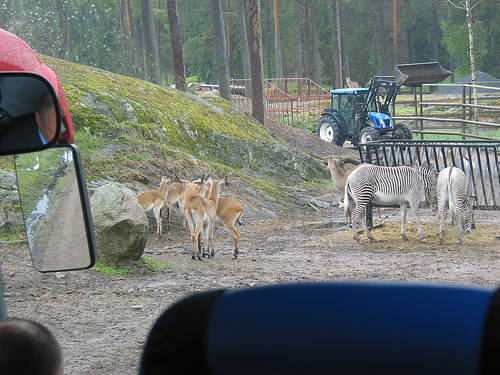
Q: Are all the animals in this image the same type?
A: No, they are antelopes and zebras.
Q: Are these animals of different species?
A: Yes, they are antelopes and zebras.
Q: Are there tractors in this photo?
A: Yes, there is a tractor.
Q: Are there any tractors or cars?
A: Yes, there is a tractor.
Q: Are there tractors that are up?
A: Yes, there is a tractor that is up.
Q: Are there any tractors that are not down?
A: Yes, there is a tractor that is up.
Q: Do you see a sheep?
A: No, there is no sheep.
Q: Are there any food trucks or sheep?
A: No, there are no sheep or food trucks.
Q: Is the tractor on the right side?
A: Yes, the tractor is on the right of the image.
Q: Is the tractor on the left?
A: No, the tractor is on the right of the image.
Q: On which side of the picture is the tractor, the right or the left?
A: The tractor is on the right of the image.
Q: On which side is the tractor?
A: The tractor is on the right of the image.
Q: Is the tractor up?
A: Yes, the tractor is up.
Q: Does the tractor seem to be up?
A: Yes, the tractor is up.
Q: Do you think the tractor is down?
A: No, the tractor is up.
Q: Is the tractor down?
A: No, the tractor is up.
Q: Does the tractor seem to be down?
A: No, the tractor is up.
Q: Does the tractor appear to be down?
A: No, the tractor is up.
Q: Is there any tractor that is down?
A: No, there is a tractor but it is up.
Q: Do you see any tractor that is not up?
A: No, there is a tractor but it is up.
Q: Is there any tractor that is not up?
A: No, there is a tractor but it is up.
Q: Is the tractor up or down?
A: The tractor is up.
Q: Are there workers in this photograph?
A: No, there are no workers.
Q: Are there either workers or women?
A: No, there are no workers or women.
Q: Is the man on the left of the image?
A: Yes, the man is on the left of the image.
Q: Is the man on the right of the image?
A: No, the man is on the left of the image.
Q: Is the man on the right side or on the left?
A: The man is on the left of the image.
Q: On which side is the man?
A: The man is on the left of the image.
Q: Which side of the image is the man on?
A: The man is on the left of the image.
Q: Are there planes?
A: No, there are no planes.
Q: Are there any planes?
A: No, there are no planes.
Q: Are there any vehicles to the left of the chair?
A: Yes, there is a vehicle to the left of the chair.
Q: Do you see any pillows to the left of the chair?
A: No, there is a vehicle to the left of the chair.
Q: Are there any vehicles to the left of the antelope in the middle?
A: Yes, there is a vehicle to the left of the antelope.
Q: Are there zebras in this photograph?
A: Yes, there is a zebra.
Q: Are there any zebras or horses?
A: Yes, there is a zebra.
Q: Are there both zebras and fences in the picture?
A: Yes, there are both a zebra and a fence.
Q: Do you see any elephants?
A: No, there are no elephants.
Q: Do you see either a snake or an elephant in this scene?
A: No, there are no elephants or snakes.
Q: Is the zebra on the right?
A: Yes, the zebra is on the right of the image.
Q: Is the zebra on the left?
A: No, the zebra is on the right of the image.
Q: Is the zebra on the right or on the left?
A: The zebra is on the right of the image.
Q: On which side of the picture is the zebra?
A: The zebra is on the right of the image.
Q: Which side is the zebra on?
A: The zebra is on the right of the image.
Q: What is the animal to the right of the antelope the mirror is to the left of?
A: The animal is a zebra.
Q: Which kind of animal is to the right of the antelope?
A: The animal is a zebra.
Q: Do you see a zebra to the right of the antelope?
A: Yes, there is a zebra to the right of the antelope.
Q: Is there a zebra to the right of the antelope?
A: Yes, there is a zebra to the right of the antelope.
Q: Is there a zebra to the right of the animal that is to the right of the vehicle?
A: Yes, there is a zebra to the right of the antelope.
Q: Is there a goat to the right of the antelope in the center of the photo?
A: No, there is a zebra to the right of the antelope.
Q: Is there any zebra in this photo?
A: Yes, there is a zebra.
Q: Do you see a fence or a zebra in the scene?
A: Yes, there is a zebra.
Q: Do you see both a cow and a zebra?
A: No, there is a zebra but no cows.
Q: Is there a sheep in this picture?
A: No, there is no sheep.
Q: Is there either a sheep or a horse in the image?
A: No, there are no sheep or horses.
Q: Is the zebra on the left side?
A: No, the zebra is on the right of the image.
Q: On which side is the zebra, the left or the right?
A: The zebra is on the right of the image.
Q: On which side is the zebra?
A: The zebra is on the right of the image.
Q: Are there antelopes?
A: Yes, there is an antelope.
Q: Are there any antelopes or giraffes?
A: Yes, there is an antelope.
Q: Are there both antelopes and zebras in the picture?
A: Yes, there are both an antelope and a zebra.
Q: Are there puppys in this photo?
A: No, there are no puppys.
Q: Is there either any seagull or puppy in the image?
A: No, there are no puppys or seagulls.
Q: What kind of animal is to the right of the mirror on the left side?
A: The animal is an antelope.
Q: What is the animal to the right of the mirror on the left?
A: The animal is an antelope.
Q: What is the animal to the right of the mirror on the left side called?
A: The animal is an antelope.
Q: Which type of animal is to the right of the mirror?
A: The animal is an antelope.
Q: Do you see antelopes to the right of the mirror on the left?
A: Yes, there is an antelope to the right of the mirror.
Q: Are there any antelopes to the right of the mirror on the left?
A: Yes, there is an antelope to the right of the mirror.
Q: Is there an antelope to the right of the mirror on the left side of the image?
A: Yes, there is an antelope to the right of the mirror.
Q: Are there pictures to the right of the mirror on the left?
A: No, there is an antelope to the right of the mirror.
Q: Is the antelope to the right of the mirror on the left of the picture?
A: Yes, the antelope is to the right of the mirror.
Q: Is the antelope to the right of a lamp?
A: No, the antelope is to the right of the mirror.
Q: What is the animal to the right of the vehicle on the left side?
A: The animal is an antelope.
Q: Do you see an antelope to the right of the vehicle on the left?
A: Yes, there is an antelope to the right of the vehicle.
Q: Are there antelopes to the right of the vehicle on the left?
A: Yes, there is an antelope to the right of the vehicle.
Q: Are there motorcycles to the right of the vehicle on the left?
A: No, there is an antelope to the right of the vehicle.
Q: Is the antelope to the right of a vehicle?
A: Yes, the antelope is to the right of a vehicle.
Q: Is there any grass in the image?
A: Yes, there is grass.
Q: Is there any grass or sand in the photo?
A: Yes, there is grass.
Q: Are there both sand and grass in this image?
A: No, there is grass but no sand.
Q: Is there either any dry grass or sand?
A: Yes, there is dry grass.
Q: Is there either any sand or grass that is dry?
A: Yes, the grass is dry.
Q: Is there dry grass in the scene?
A: Yes, there is dry grass.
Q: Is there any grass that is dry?
A: Yes, there is grass that is dry.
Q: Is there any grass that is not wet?
A: Yes, there is dry grass.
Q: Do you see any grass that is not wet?
A: Yes, there is dry grass.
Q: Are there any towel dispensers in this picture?
A: No, there are no towel dispensers.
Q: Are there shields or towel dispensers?
A: No, there are no towel dispensers or shields.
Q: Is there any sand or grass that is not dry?
A: No, there is grass but it is dry.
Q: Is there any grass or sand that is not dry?
A: No, there is grass but it is dry.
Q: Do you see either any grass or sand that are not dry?
A: No, there is grass but it is dry.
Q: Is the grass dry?
A: Yes, the grass is dry.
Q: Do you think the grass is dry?
A: Yes, the grass is dry.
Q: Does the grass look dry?
A: Yes, the grass is dry.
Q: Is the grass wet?
A: No, the grass is dry.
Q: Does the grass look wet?
A: No, the grass is dry.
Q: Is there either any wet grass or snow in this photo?
A: No, there is grass but it is dry.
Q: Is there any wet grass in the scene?
A: No, there is grass but it is dry.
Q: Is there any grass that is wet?
A: No, there is grass but it is dry.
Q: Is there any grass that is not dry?
A: No, there is grass but it is dry.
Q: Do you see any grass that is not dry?
A: No, there is grass but it is dry.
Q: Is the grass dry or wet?
A: The grass is dry.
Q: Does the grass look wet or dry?
A: The grass is dry.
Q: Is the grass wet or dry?
A: The grass is dry.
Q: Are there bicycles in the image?
A: No, there are no bicycles.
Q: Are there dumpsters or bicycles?
A: No, there are no bicycles or dumpsters.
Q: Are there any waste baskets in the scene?
A: No, there are no waste baskets.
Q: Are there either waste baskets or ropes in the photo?
A: No, there are no waste baskets or ropes.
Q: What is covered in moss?
A: The rock is covered in moss.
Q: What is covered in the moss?
A: The rock is covered in moss.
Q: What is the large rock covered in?
A: The rock is covered in moss.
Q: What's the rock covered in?
A: The rock is covered in moss.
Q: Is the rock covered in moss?
A: Yes, the rock is covered in moss.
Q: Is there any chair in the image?
A: Yes, there is a chair.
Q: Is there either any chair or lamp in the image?
A: Yes, there is a chair.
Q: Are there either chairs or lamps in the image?
A: Yes, there is a chair.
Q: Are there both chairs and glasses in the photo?
A: No, there is a chair but no glasses.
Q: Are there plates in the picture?
A: No, there are no plates.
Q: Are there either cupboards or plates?
A: No, there are no plates or cupboards.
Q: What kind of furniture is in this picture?
A: The furniture is a chair.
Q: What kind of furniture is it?
A: The piece of furniture is a chair.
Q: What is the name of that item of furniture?
A: This is a chair.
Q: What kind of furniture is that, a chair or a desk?
A: This is a chair.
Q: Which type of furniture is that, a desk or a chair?
A: This is a chair.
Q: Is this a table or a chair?
A: This is a chair.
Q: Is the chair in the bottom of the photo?
A: Yes, the chair is in the bottom of the image.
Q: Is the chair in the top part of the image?
A: No, the chair is in the bottom of the image.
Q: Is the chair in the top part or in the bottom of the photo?
A: The chair is in the bottom of the image.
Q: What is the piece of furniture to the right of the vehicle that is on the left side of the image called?
A: The piece of furniture is a chair.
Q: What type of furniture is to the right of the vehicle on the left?
A: The piece of furniture is a chair.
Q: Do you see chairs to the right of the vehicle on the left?
A: Yes, there is a chair to the right of the vehicle.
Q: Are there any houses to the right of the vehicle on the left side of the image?
A: No, there is a chair to the right of the vehicle.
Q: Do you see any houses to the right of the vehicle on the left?
A: No, there is a chair to the right of the vehicle.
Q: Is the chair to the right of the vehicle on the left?
A: Yes, the chair is to the right of the vehicle.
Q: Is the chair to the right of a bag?
A: No, the chair is to the right of the vehicle.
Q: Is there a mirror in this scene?
A: Yes, there is a mirror.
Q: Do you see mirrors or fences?
A: Yes, there is a mirror.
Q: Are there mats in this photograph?
A: No, there are no mats.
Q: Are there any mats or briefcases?
A: No, there are no mats or briefcases.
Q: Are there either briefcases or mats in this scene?
A: No, there are no mats or briefcases.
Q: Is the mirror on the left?
A: Yes, the mirror is on the left of the image.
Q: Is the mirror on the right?
A: No, the mirror is on the left of the image.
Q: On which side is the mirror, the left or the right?
A: The mirror is on the left of the image.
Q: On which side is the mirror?
A: The mirror is on the left of the image.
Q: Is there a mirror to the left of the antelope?
A: Yes, there is a mirror to the left of the antelope.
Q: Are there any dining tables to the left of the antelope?
A: No, there is a mirror to the left of the antelope.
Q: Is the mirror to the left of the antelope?
A: Yes, the mirror is to the left of the antelope.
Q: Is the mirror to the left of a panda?
A: No, the mirror is to the left of the antelope.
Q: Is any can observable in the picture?
A: No, there are no cans.